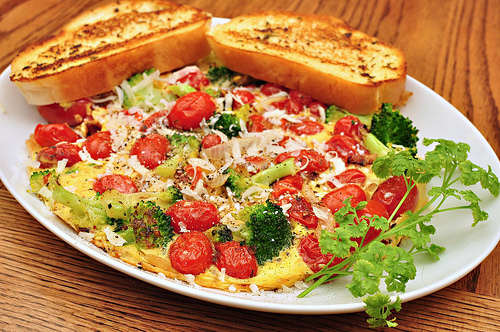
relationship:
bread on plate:
[225, 17, 397, 98] [412, 114, 483, 136]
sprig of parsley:
[391, 145, 481, 244] [323, 218, 419, 297]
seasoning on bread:
[106, 22, 135, 47] [225, 17, 397, 98]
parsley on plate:
[323, 218, 419, 297] [412, 114, 483, 136]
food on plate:
[51, 4, 468, 304] [412, 114, 483, 136]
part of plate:
[1, 94, 29, 120] [412, 114, 483, 136]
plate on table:
[412, 114, 483, 136] [414, 8, 483, 62]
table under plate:
[414, 8, 483, 62] [412, 114, 483, 136]